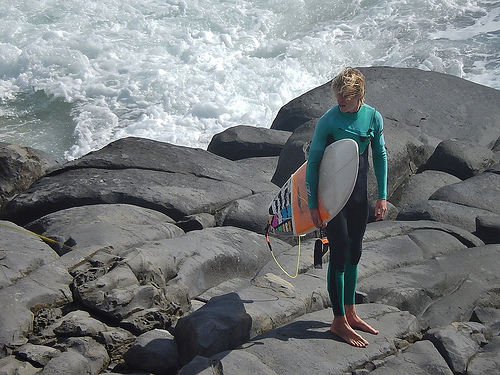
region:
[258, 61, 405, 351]
person wearing a wet suit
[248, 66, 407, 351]
person carrying a surfboard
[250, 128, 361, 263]
white surfboard with design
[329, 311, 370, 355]
foot of a person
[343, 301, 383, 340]
foot of a person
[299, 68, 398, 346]
person wearing green and black wet suit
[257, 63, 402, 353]
person with blonde hair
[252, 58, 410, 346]
person carrying white surfboard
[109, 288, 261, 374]
shadow of a surfboard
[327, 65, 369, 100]
blonde hair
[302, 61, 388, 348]
Man standing on top of rocks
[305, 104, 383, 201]
Green and black top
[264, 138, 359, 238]
Orange, black and white surfboard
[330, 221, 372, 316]
Black and green legging of surfer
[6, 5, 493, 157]
Waves crashing against the rocks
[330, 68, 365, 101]
Blonde hair of surfer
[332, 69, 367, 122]
Head of surfer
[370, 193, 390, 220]
Left hand of surfer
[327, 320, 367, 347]
Right foot of surfer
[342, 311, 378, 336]
Left foot of surfer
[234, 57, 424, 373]
person carrying a surfboard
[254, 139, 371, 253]
surfboard with designs on it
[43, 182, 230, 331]
gray rocks on the shore of the ocean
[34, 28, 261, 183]
water crashing to the rocks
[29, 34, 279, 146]
water crashing to the shore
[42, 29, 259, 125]
white foam on the ocean waves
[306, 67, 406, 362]
man in a wet suit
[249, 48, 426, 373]
man with hair blowing in the wind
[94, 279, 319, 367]
shadow of a man on the rocks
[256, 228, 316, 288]
strap on the surfboard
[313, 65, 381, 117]
The person is a blonde.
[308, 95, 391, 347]
The wetsuit is green and black.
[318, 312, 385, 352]
The person isn't wearing shoes.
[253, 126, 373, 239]
Surfboard under the person's arm.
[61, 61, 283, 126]
White foam on the water.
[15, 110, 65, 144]
Grey part of the water.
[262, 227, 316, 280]
Rope on the surfboard.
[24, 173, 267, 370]
The rocks are dark grey.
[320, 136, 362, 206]
Part of the surfboard is white.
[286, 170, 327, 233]
Orange on the surfboard.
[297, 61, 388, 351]
man is black and green wetsuit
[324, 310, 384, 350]
no shoes on feet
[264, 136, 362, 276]
multicolored surfboard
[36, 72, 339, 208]
rocks on edge of sea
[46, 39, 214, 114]
white water from surf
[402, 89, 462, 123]
dark grey rocks by sea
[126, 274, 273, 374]
shadow on the rocks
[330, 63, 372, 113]
man has blonde hair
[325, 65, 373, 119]
wind is blowing hair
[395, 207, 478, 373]
multiple cracks in rocks